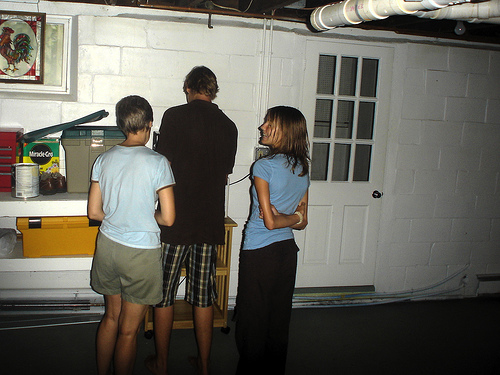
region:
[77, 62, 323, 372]
Three people in the foreground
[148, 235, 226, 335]
Young man is wearing shorts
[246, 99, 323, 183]
A side view of a woman's head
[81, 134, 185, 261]
Person is wearing a light blue shirt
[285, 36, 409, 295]
A white door in the background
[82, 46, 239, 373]
A back view of two people's heads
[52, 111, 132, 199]
Container on the table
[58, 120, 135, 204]
Container is gray in color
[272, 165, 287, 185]
the shirt is blue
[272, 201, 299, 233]
her arms are folded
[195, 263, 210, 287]
the shorts are plaid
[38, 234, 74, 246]
the container is yellow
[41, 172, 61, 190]
the shoes are brown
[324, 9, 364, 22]
the pipe is white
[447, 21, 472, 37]
the light is off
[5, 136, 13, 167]
the toolbox is red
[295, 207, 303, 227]
BRACELET ON THE ARM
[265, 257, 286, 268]
WOMAN HAS ON BLACK PANTS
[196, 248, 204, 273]
MAN HAS ON PLAID SHORTS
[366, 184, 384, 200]
DOOR KNOB ON THE DOOR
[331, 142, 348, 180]
GLASS IN THE DOOR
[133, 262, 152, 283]
PERSON HAS ON BROWN SHORTS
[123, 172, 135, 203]
PERSON HAS ON A LIGHT GREEN SHIRT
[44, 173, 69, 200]
SHOES ON THE COUNTER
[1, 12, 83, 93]
PICTURE ON THE WALL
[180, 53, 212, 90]
man has brown hair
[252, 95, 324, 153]
woman has brown hair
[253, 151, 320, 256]
woman has blue shirt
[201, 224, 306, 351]
woman has black pants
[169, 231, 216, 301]
man has checked shorts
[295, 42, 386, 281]
white door behind people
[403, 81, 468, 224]
wall is white brick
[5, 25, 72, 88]
stained glass painting on wall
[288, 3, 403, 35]
white pipe on ceiling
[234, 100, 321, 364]
this is a person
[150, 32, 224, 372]
this is a person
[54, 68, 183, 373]
this is a person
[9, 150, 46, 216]
this is a tin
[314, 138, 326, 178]
this is a window pane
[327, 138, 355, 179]
this is a window pane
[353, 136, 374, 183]
this is a window pane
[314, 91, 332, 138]
this is a window pane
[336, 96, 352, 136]
this is a window pane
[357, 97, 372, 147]
this is a window pane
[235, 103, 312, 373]
a girl in a blue t-shirt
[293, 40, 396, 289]
the closed white door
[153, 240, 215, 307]
the checkered shorts the teenager is wearing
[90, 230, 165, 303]
the gray shorts on the boy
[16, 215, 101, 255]
the yellow container on the shelf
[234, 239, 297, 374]
the black pants on the girl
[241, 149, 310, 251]
the blue t-shirt on the girl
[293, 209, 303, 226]
the bracelet on the girl's wrist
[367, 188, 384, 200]
Handle on a door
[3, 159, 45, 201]
Paint can on a table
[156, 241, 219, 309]
Plaid shorts on a man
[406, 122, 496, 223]
Wall made of bricks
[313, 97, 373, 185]
Windows on a door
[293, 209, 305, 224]
Bracelet on a woman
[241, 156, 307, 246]
Blue shirt on a woman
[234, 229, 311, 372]
Black pants on a woman